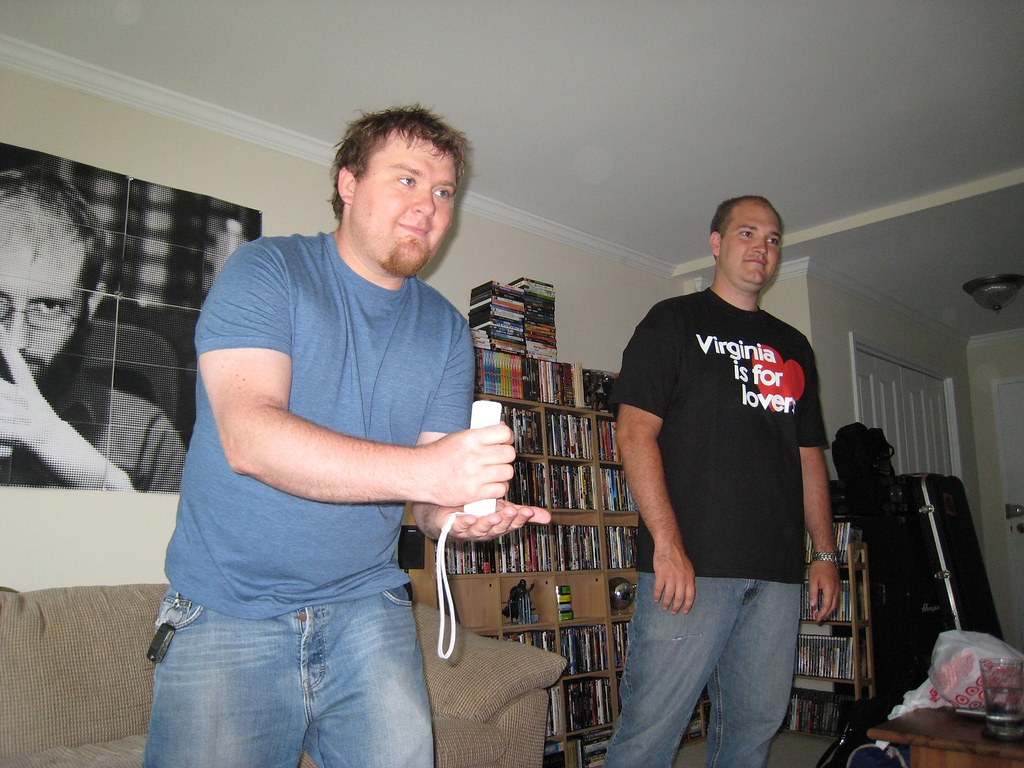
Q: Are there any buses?
A: No, there are no buses.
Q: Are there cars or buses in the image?
A: No, there are no buses or cars.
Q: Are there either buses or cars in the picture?
A: No, there are no buses or cars.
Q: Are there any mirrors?
A: No, there are no mirrors.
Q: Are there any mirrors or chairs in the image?
A: No, there are no mirrors or chairs.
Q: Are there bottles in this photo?
A: No, there are no bottles.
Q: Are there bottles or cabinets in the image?
A: No, there are no bottles or cabinets.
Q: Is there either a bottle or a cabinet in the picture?
A: No, there are no bottles or cabinets.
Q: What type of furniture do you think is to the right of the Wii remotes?
A: The piece of furniture is a shelf.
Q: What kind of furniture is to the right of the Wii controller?
A: The piece of furniture is a shelf.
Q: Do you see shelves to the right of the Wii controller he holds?
A: Yes, there is a shelf to the right of the Wii remotes.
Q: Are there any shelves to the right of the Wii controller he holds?
A: Yes, there is a shelf to the right of the Wii remotes.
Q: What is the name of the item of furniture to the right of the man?
A: The piece of furniture is a shelf.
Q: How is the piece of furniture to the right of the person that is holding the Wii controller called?
A: The piece of furniture is a shelf.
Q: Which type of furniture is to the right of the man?
A: The piece of furniture is a shelf.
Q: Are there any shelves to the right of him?
A: Yes, there is a shelf to the right of the man.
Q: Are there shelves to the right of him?
A: Yes, there is a shelf to the right of the man.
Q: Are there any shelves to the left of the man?
A: No, the shelf is to the right of the man.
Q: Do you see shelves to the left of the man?
A: No, the shelf is to the right of the man.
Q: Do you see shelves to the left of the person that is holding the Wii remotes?
A: No, the shelf is to the right of the man.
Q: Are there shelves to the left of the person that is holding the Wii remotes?
A: No, the shelf is to the right of the man.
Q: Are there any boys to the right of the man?
A: No, there is a shelf to the right of the man.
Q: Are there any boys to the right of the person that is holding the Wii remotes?
A: No, there is a shelf to the right of the man.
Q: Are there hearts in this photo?
A: Yes, there is a heart.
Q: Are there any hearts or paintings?
A: Yes, there is a heart.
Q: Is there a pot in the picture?
A: No, there are no pots.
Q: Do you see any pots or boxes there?
A: No, there are no pots or boxes.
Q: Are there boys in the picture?
A: No, there are no boys.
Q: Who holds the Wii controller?
A: The man holds the Wii controller.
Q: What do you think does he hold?
A: The man holds the Wii remotes.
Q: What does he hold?
A: The man holds the Wii remotes.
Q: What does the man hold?
A: The man holds the Wii remotes.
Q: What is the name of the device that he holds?
A: The device is a Wii controller.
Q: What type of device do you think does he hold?
A: The man holds the Wii controller.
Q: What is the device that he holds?
A: The device is a Wii controller.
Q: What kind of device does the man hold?
A: The man holds the Wii controller.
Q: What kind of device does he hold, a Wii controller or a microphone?
A: The man holds a Wii controller.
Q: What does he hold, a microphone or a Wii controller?
A: The man holds a Wii controller.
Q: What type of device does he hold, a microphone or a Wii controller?
A: The man holds a Wii controller.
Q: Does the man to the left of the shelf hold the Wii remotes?
A: Yes, the man holds the Wii remotes.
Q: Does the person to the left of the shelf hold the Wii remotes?
A: Yes, the man holds the Wii remotes.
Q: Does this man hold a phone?
A: No, the man holds the Wii remotes.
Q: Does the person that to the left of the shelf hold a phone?
A: No, the man holds the Wii remotes.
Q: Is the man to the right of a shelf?
A: No, the man is to the left of a shelf.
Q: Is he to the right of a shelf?
A: No, the man is to the left of a shelf.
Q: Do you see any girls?
A: No, there are no girls.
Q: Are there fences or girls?
A: No, there are no girls or fences.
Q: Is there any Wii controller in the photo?
A: Yes, there is a Wii controller.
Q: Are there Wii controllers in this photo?
A: Yes, there is a Wii controller.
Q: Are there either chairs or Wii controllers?
A: Yes, there is a Wii controller.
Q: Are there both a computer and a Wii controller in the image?
A: No, there is a Wii controller but no computers.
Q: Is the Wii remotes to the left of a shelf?
A: Yes, the Wii remotes is to the left of a shelf.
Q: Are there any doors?
A: Yes, there is a door.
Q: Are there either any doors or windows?
A: Yes, there is a door.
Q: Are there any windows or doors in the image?
A: Yes, there is a door.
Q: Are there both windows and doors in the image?
A: No, there is a door but no windows.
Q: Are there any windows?
A: No, there are no windows.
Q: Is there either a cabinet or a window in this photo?
A: No, there are no windows or cabinets.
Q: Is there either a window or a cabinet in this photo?
A: No, there are no windows or cabinets.